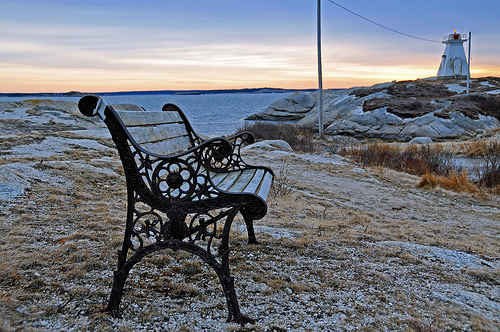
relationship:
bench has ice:
[76, 94, 274, 325] [95, 103, 271, 203]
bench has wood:
[76, 94, 274, 325] [116, 110, 274, 200]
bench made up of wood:
[76, 94, 274, 325] [116, 110, 274, 200]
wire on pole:
[328, 0, 475, 53] [309, 5, 337, 135]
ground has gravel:
[7, 163, 494, 331] [5, 260, 399, 324]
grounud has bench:
[7, 163, 494, 331] [76, 94, 274, 325]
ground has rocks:
[7, 163, 494, 331] [0, 101, 289, 319]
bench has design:
[76, 94, 274, 325] [120, 137, 237, 269]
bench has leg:
[76, 94, 274, 325] [106, 262, 256, 326]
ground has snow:
[7, 163, 494, 331] [95, 99, 119, 121]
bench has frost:
[76, 94, 274, 325] [95, 103, 271, 203]